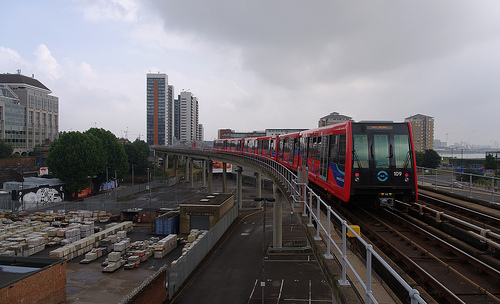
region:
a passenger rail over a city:
[18, 32, 457, 288]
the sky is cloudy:
[137, 32, 464, 102]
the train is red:
[193, 109, 455, 231]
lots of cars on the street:
[9, 197, 201, 284]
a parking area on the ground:
[184, 164, 299, 294]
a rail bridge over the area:
[164, 136, 410, 298]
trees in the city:
[40, 127, 175, 190]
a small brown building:
[163, 176, 240, 241]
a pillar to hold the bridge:
[262, 175, 288, 255]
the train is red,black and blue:
[295, 112, 431, 218]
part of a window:
[346, 142, 365, 158]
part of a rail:
[347, 219, 363, 234]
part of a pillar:
[273, 225, 281, 250]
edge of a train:
[328, 150, 330, 155]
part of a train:
[363, 123, 373, 131]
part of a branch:
[83, 180, 90, 189]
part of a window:
[378, 152, 392, 171]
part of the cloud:
[268, 37, 280, 52]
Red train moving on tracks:
[291, 115, 436, 225]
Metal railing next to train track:
[345, 231, 393, 284]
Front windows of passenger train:
[353, 131, 414, 177]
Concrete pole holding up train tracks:
[264, 199, 289, 249]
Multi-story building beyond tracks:
[142, 70, 173, 130]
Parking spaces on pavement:
[243, 272, 316, 300]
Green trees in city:
[83, 124, 131, 200]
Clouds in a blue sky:
[102, 13, 192, 48]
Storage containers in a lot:
[47, 215, 124, 246]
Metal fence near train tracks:
[195, 231, 220, 260]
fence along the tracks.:
[335, 240, 362, 274]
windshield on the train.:
[378, 136, 386, 163]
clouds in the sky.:
[284, 43, 369, 89]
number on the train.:
[390, 168, 405, 176]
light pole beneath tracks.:
[255, 196, 273, 256]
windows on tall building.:
[160, 78, 164, 134]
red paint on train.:
[334, 190, 343, 195]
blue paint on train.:
[334, 170, 345, 181]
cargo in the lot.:
[25, 232, 45, 255]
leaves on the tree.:
[74, 138, 102, 163]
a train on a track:
[185, 54, 488, 229]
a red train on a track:
[180, 93, 433, 240]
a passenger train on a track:
[171, 64, 493, 262]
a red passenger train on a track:
[210, 51, 490, 276]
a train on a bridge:
[261, 98, 472, 258]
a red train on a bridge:
[205, 126, 495, 274]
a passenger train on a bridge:
[200, 76, 492, 299]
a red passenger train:
[187, 90, 499, 284]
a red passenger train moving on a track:
[217, 89, 457, 292]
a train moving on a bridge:
[173, 105, 478, 271]